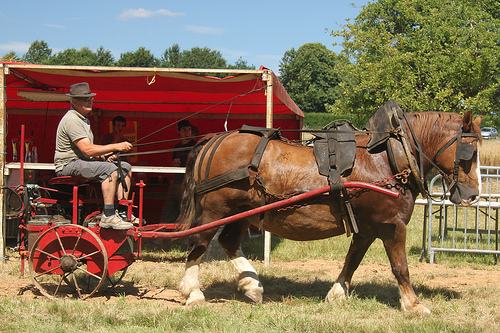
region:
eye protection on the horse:
[453, 137, 478, 164]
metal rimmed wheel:
[28, 223, 108, 295]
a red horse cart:
[19, 161, 151, 296]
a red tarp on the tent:
[3, 61, 308, 146]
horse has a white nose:
[466, 145, 486, 195]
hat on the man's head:
[63, 81, 100, 101]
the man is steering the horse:
[51, 80, 140, 235]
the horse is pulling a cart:
[18, 82, 480, 308]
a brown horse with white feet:
[186, 111, 486, 309]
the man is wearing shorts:
[50, 154, 131, 185]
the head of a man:
[67, 58, 114, 123]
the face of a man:
[72, 83, 112, 113]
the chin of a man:
[72, 95, 112, 124]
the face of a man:
[61, 94, 107, 121]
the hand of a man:
[102, 123, 159, 165]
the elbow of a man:
[67, 135, 105, 162]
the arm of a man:
[70, 113, 142, 169]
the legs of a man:
[69, 150, 146, 252]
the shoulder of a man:
[36, 85, 93, 169]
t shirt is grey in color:
[55, 111, 83, 149]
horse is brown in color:
[259, 144, 434, 227]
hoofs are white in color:
[233, 258, 267, 305]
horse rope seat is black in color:
[304, 122, 366, 172]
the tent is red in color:
[116, 53, 286, 118]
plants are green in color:
[394, 9, 474, 110]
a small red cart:
[14, 175, 150, 304]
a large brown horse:
[165, 108, 487, 309]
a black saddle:
[307, 114, 356, 182]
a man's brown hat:
[63, 79, 94, 99]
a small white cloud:
[113, 4, 183, 23]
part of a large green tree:
[327, 0, 497, 137]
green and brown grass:
[420, 250, 496, 332]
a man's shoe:
[100, 210, 140, 229]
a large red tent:
[2, 57, 304, 219]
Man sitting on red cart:
[52, 81, 146, 228]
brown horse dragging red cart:
[170, 104, 482, 316]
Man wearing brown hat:
[55, 79, 146, 231]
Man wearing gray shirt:
[50, 82, 141, 232]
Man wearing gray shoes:
[53, 79, 147, 233]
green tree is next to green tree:
[276, 44, 353, 109]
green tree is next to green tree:
[326, 2, 497, 134]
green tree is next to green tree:
[118, 45, 160, 66]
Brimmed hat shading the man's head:
[62, 82, 96, 98]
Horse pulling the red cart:
[172, 109, 483, 319]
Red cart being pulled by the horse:
[19, 123, 411, 301]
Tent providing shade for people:
[0, 60, 305, 266]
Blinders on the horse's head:
[457, 141, 474, 161]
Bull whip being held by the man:
[100, 81, 278, 162]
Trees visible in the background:
[1, 0, 498, 112]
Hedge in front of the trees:
[301, 111, 498, 133]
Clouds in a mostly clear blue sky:
[0, 6, 282, 59]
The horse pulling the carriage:
[187, 106, 484, 311]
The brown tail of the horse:
[175, 132, 214, 229]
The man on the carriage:
[51, 83, 151, 232]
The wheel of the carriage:
[29, 221, 110, 301]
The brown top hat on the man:
[63, 81, 99, 99]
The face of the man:
[71, 93, 94, 113]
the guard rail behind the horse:
[424, 166, 499, 262]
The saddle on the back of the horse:
[309, 116, 357, 205]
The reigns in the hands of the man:
[114, 125, 384, 188]